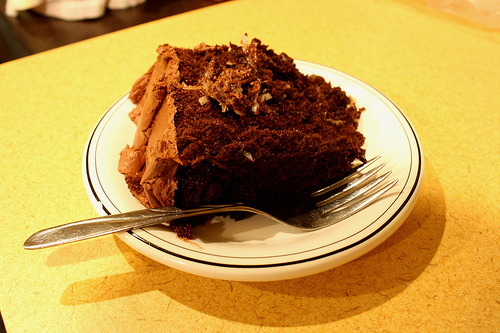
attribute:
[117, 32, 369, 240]
cake — food, brown, chocolate, dark brown, sliced, dessert, triangular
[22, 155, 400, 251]
fork — silver, metal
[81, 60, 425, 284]
plate — white, blue, ceramic, round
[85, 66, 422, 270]
ring — black, blue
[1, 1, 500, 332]
table — tan, yellowish, wooden, brown, light tan, yellow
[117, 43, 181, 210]
frosting — light brown, chocolate, brown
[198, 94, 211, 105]
piece — white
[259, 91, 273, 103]
piece — white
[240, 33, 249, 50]
piece — white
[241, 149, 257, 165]
piece — white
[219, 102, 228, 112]
piece — white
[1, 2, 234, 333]
floor — dark brown